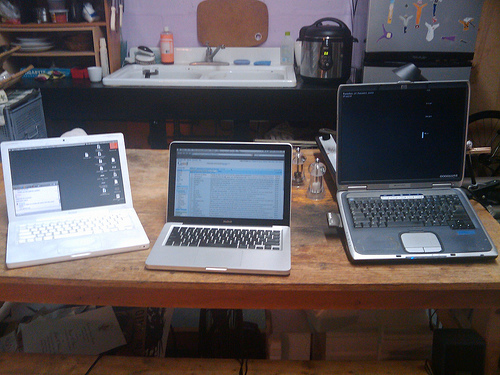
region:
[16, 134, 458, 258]
three open laptop computers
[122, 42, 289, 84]
white double sink with a silver faucet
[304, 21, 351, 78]
silver and black countertop appliance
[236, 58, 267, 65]
two bars of blue soap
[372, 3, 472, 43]
silver refrigerator with magnets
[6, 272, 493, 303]
wooden table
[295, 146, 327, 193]
salt and pepper shakers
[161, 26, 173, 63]
orange bottle of soap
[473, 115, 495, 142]
bicycle wheel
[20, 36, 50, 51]
stack of white dishes on a shelf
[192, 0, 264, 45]
brown cutting board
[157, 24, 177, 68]
dish soap sitting on sink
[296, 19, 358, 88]
a silver slow cooker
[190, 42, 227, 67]
a silver sink facet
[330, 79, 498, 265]
black and silver laptop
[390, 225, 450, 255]
laptop touch pad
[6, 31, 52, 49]
stack of white plates on shelf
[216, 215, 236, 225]
company logo on front of laptop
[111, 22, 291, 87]
white kitchen sink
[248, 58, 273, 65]
blue dish sponge on sink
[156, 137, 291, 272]
Newer-looking Laptop Computer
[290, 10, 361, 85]
High-Quality Rice Cooker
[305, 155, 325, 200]
Fancy Glass Salt Shaker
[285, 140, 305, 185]
Fancy Glass Pepper Shaker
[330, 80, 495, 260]
Old, Heavy Laptop Computer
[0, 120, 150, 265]
Newer Mac Laptop Computer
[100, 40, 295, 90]
White Double Sink with Soap and Sponges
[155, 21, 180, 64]
Bottle of Hand Soap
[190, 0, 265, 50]
Small Wooden Cutting Board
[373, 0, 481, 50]
Group of Refrigerator Magnets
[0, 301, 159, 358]
piles of paper in trashcan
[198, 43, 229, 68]
silver sink faucet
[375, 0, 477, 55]
stickers on refrigerator door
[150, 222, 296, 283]
silver laptop keyboard with black keys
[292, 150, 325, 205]
clear glass salt and pepper shakers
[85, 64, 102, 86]
white cup sitting on counter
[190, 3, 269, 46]
brown wooden cutting board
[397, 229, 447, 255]
touch pad on laptop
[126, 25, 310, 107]
the sink is white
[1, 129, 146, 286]
the laptop is white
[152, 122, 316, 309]
the laptop is gray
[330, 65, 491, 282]
the laptop is gray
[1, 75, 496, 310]
the laptops are on a wooden surface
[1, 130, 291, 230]
2 of the laptops are on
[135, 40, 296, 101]
the sink is dirty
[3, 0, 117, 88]
the shelf is brown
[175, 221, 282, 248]
the keyboard is black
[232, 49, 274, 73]
soap is on the sink